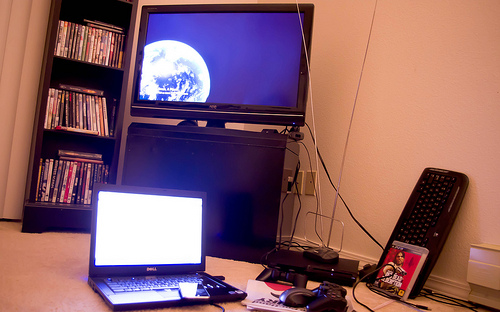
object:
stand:
[169, 89, 314, 143]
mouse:
[278, 286, 313, 307]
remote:
[306, 280, 346, 305]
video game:
[371, 239, 427, 301]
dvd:
[29, 17, 125, 206]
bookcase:
[22, 1, 142, 235]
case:
[367, 239, 432, 304]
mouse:
[250, 281, 331, 309]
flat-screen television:
[125, 2, 318, 127]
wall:
[340, 156, 405, 200]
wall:
[2, 0, 25, 211]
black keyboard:
[368, 166, 470, 300]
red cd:
[371, 239, 431, 296]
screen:
[93, 190, 201, 265]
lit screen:
[95, 189, 201, 264]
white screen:
[94, 187, 207, 268]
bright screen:
[93, 190, 205, 266]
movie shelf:
[23, 4, 139, 230]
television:
[130, 2, 321, 127]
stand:
[117, 122, 299, 263]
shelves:
[17, 15, 125, 263]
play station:
[304, 278, 346, 310]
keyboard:
[368, 166, 471, 300]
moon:
[137, 37, 214, 104]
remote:
[247, 283, 301, 310]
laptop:
[87, 181, 247, 310]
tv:
[127, 2, 314, 127]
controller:
[309, 279, 348, 311]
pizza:
[127, 3, 322, 125]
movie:
[371, 237, 431, 302]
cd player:
[264, 246, 359, 286]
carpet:
[1, 221, 483, 312]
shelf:
[22, 0, 142, 234]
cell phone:
[177, 281, 212, 299]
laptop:
[263, 245, 363, 288]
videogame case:
[374, 239, 429, 293]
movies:
[55, 19, 124, 67]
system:
[266, 242, 363, 287]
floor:
[0, 232, 497, 312]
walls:
[321, 1, 498, 283]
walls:
[1, 2, 41, 227]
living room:
[2, 1, 495, 306]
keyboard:
[88, 257, 263, 308]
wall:
[293, 23, 497, 263]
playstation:
[257, 246, 358, 288]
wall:
[6, 6, 493, 300]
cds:
[35, 16, 123, 204]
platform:
[121, 121, 297, 263]